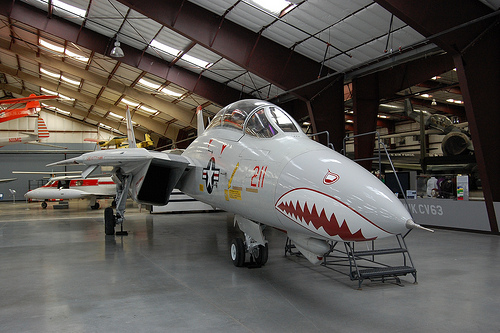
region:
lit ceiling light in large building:
[246, 1, 296, 19]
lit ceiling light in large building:
[51, 2, 86, 22]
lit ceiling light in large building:
[35, 41, 64, 61]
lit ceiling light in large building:
[63, 49, 88, 64]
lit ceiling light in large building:
[38, 68, 60, 81]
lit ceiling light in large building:
[61, 75, 81, 88]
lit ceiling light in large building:
[58, 93, 77, 102]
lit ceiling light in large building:
[149, 41, 180, 59]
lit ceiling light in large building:
[183, 51, 211, 69]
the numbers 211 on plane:
[244, 160, 279, 197]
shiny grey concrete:
[25, 262, 186, 320]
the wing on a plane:
[18, 151, 219, 166]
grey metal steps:
[333, 238, 430, 305]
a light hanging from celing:
[97, 29, 134, 68]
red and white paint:
[266, 183, 383, 250]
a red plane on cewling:
[2, 80, 64, 122]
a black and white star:
[180, 151, 232, 201]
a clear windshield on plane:
[207, 87, 312, 144]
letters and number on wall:
[408, 191, 462, 223]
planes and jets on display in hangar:
[8, 6, 485, 313]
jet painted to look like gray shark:
[176, 96, 437, 276]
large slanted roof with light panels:
[13, 7, 440, 147]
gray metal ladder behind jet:
[287, 125, 423, 288]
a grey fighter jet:
[51, 99, 438, 277]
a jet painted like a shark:
[35, 97, 437, 295]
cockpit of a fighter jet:
[205, 97, 300, 144]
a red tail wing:
[22, 92, 44, 121]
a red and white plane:
[25, 170, 118, 202]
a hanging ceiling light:
[106, 35, 126, 62]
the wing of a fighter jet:
[46, 143, 189, 211]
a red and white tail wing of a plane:
[31, 118, 53, 143]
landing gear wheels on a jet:
[229, 213, 269, 270]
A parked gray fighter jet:
[50, 82, 437, 276]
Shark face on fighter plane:
[275, 136, 435, 256]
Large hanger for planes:
[2, 2, 493, 332]